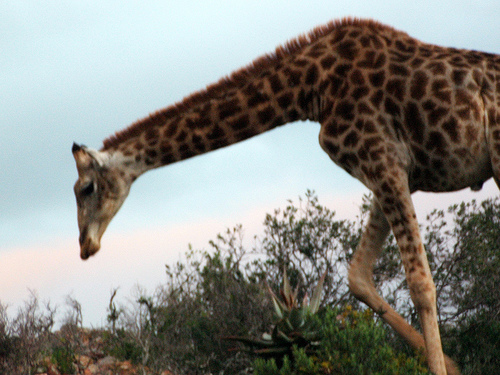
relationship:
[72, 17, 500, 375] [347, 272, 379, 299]
giraffe has a kneecap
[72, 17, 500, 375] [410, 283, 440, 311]
giraffe has a kneecap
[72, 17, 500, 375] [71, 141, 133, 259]
giraffe has a head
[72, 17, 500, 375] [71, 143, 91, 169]
giraffe has horns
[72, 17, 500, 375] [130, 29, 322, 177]
giraffe has a neck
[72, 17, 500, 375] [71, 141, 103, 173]
giraffe has ears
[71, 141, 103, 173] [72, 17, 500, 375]
ears are on giraffe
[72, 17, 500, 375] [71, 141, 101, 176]
giraffe has a ears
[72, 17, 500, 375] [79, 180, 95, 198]
giraffe has a eye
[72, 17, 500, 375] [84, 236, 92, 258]
giraffe has a mouth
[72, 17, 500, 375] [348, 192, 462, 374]
giraffe has leg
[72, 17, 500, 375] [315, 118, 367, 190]
giraffe has a chest